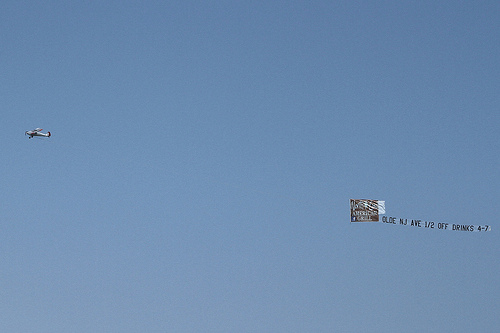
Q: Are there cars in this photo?
A: No, there are no cars.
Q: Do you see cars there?
A: No, there are no cars.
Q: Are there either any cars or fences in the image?
A: No, there are no cars or fences.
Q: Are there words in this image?
A: Yes, there are words.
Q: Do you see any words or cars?
A: Yes, there are words.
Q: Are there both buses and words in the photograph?
A: No, there are words but no buses.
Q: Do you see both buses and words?
A: No, there are words but no buses.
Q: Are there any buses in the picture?
A: No, there are no buses.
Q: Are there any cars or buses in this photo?
A: No, there are no buses or cars.